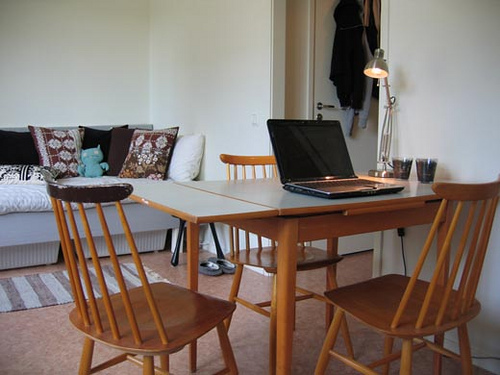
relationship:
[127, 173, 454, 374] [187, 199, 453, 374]
table has wood base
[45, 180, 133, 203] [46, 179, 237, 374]
black top on chair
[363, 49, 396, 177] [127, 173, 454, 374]
table lamp on table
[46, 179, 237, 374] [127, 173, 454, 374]
chair by table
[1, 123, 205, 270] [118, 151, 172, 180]
couch has pillow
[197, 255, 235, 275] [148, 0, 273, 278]
slipper next to wall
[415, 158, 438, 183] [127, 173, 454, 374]
cup on table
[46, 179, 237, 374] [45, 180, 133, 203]
chair has black top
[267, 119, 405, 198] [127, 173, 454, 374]
lap top on table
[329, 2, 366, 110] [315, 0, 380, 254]
sweatshirt hanging on door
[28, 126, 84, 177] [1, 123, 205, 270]
pillow on couch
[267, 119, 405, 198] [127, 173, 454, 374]
lap top sitting on table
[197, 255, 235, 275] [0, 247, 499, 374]
slipper on floor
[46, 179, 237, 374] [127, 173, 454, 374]
chair at table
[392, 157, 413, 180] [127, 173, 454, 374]
cup on table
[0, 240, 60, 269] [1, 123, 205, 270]
container under couch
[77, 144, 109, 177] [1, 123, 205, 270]
stuffed animal on couch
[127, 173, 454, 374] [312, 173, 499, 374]
table has chair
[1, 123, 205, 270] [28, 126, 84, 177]
couch has pillow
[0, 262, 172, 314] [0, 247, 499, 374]
runner on floor